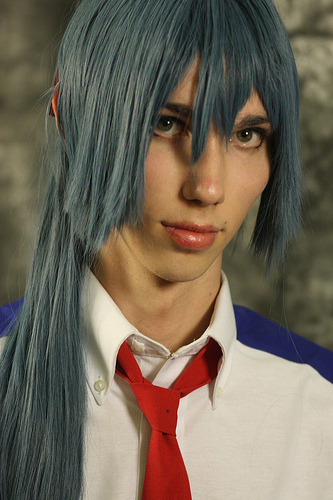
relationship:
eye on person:
[145, 107, 191, 137] [30, 3, 331, 498]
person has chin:
[30, 3, 331, 498] [138, 250, 228, 283]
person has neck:
[30, 3, 331, 498] [91, 225, 233, 360]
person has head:
[30, 3, 331, 498] [49, 3, 291, 290]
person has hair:
[30, 3, 331, 498] [0, 0, 304, 498]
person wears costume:
[30, 3, 331, 498] [9, 283, 325, 491]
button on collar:
[90, 377, 105, 394] [91, 303, 230, 411]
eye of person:
[231, 98, 282, 176] [30, 3, 331, 498]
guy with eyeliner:
[0, 0, 332, 499] [142, 95, 274, 152]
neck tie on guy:
[122, 336, 224, 498] [0, 0, 332, 499]